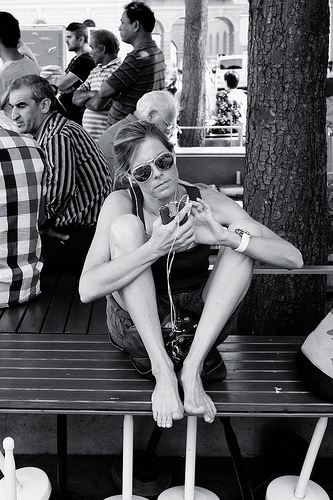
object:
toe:
[188, 405, 207, 417]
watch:
[231, 228, 251, 253]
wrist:
[220, 227, 239, 249]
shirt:
[34, 109, 113, 244]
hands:
[149, 197, 227, 256]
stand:
[205, 54, 248, 94]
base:
[176, 125, 242, 147]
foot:
[150, 370, 184, 428]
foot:
[178, 364, 217, 424]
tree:
[236, 0, 331, 354]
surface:
[0, 297, 333, 417]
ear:
[121, 164, 137, 184]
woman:
[78, 118, 304, 428]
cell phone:
[158, 201, 197, 255]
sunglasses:
[132, 152, 175, 184]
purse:
[122, 310, 238, 381]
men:
[53, 22, 96, 127]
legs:
[109, 214, 184, 429]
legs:
[177, 219, 261, 424]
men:
[72, 29, 123, 143]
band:
[231, 233, 251, 253]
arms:
[47, 51, 151, 113]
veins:
[153, 372, 202, 409]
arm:
[184, 187, 305, 270]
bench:
[0, 247, 333, 499]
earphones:
[127, 177, 189, 326]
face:
[128, 137, 178, 200]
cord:
[132, 186, 139, 218]